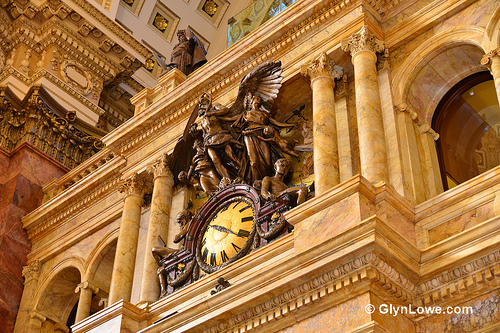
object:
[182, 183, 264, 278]
clock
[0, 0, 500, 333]
building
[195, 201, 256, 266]
roman numerals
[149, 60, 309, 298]
statue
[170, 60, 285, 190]
wings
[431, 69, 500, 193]
window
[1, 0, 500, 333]
gold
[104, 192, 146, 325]
pillars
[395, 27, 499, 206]
arches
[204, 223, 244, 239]
hands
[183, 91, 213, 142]
sword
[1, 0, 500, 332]
stone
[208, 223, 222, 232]
minute hand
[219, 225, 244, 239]
hour hand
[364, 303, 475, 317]
water mark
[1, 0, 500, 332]
picture